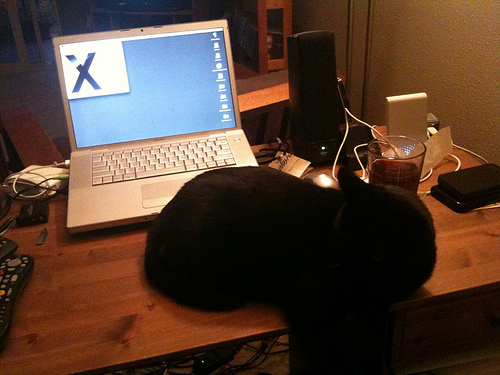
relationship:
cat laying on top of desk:
[138, 159, 443, 325] [52, 249, 121, 336]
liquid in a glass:
[377, 156, 415, 185] [365, 132, 428, 199]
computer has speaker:
[54, 32, 242, 158] [154, 25, 164, 29]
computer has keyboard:
[53, 18, 258, 234] [94, 145, 237, 169]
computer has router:
[54, 32, 242, 158] [2, 160, 65, 202]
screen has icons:
[130, 53, 185, 83] [203, 30, 233, 130]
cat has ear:
[138, 159, 443, 325] [336, 165, 361, 198]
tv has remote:
[101, 6, 186, 14] [0, 252, 36, 339]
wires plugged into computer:
[41, 177, 66, 194] [54, 32, 242, 158]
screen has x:
[130, 53, 185, 83] [65, 48, 106, 100]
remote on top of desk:
[6, 251, 37, 276] [52, 249, 121, 336]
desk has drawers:
[52, 249, 121, 336] [415, 308, 498, 360]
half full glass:
[373, 158, 416, 176] [365, 132, 428, 199]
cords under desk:
[234, 347, 275, 368] [52, 249, 121, 336]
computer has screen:
[53, 18, 258, 234] [130, 53, 185, 83]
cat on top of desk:
[138, 159, 443, 325] [52, 249, 121, 336]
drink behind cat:
[365, 132, 428, 199] [138, 159, 443, 325]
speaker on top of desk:
[154, 25, 164, 29] [52, 249, 121, 336]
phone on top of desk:
[7, 172, 54, 188] [52, 249, 121, 336]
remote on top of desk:
[0, 252, 36, 339] [52, 249, 121, 336]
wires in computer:
[41, 177, 66, 194] [53, 18, 258, 234]